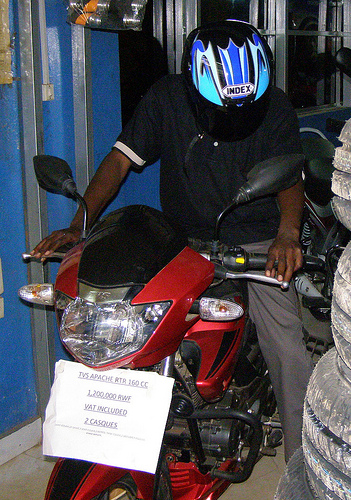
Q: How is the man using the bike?
A: He is sitting on it.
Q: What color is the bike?
A: Red.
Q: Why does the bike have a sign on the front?
A: It is for sale.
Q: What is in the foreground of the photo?
A: Tires.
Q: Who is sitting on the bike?
A: A man.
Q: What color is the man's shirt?
A: Black.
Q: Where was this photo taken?
A: In a garage.